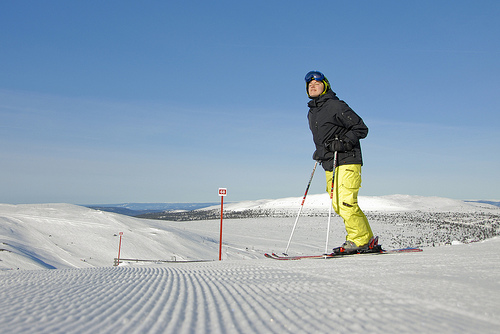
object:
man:
[302, 69, 386, 256]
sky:
[0, 0, 499, 207]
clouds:
[15, 139, 478, 203]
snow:
[0, 192, 500, 334]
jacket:
[306, 87, 369, 172]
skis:
[264, 247, 424, 261]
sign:
[217, 187, 228, 197]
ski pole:
[323, 150, 338, 256]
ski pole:
[283, 159, 319, 253]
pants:
[325, 163, 374, 248]